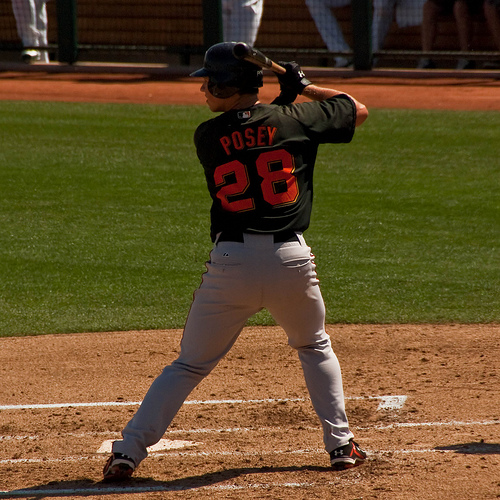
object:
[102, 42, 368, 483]
baseball player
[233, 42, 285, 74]
baseball bat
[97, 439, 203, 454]
baseball plate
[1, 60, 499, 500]
ground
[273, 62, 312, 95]
glove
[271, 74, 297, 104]
glove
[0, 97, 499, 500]
field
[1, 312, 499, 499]
patch of dirt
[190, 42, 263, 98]
baseball helmet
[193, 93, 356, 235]
baseball jersey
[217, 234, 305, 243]
belt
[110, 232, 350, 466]
baseball pants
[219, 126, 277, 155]
posey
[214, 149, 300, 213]
number 28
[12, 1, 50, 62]
player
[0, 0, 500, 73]
dugout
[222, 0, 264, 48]
player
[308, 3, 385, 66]
player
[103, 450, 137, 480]
sneaker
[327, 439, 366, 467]
sneaker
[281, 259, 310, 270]
hind pocket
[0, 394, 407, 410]
white line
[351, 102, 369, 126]
elbow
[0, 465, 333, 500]
shadow